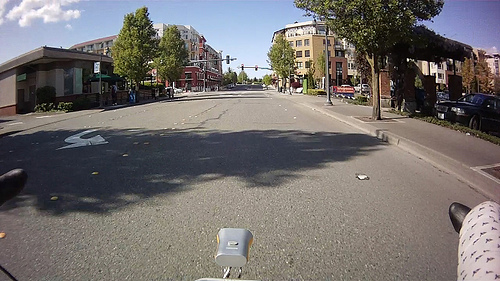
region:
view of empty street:
[23, 10, 468, 261]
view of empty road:
[25, 16, 434, 275]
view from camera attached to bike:
[72, 26, 382, 278]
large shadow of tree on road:
[17, 90, 372, 228]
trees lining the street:
[107, 7, 422, 119]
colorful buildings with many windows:
[83, 20, 377, 110]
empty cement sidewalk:
[307, 79, 492, 186]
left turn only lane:
[39, 115, 160, 193]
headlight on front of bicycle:
[193, 210, 285, 270]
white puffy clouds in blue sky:
[0, 0, 87, 37]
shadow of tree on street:
[19, 120, 384, 214]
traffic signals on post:
[237, 60, 275, 74]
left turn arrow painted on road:
[58, 120, 121, 152]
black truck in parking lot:
[434, 87, 494, 139]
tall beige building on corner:
[275, 33, 336, 98]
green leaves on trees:
[111, 9, 151, 89]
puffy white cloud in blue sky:
[2, 6, 93, 32]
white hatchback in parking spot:
[353, 78, 371, 95]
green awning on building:
[92, 68, 126, 87]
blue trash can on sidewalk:
[127, 90, 140, 105]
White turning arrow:
[56, 112, 118, 169]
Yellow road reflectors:
[88, 163, 101, 181]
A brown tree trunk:
[363, 63, 386, 123]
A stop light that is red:
[231, 57, 276, 77]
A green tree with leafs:
[111, 3, 158, 120]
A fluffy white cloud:
[0, 0, 87, 37]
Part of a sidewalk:
[392, 105, 491, 180]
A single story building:
[0, 42, 113, 124]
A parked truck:
[433, 80, 498, 135]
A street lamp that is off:
[308, 18, 339, 110]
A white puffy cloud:
[0, 0, 97, 44]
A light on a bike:
[214, 219, 257, 276]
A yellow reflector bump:
[115, 148, 132, 167]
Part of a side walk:
[404, 110, 488, 171]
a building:
[0, 51, 116, 124]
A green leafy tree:
[116, 3, 154, 105]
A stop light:
[235, 58, 295, 95]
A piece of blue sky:
[220, 4, 267, 58]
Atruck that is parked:
[436, 81, 498, 136]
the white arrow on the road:
[55, 120, 105, 150]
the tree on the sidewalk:
[295, 0, 445, 120]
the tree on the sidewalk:
[265, 30, 295, 90]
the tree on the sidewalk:
[110, 5, 150, 95]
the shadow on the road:
[5, 125, 385, 210]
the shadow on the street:
[5, 120, 385, 205]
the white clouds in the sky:
[0, 0, 80, 30]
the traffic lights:
[187, 50, 272, 87]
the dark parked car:
[430, 86, 495, 131]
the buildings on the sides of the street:
[3, 17, 498, 114]